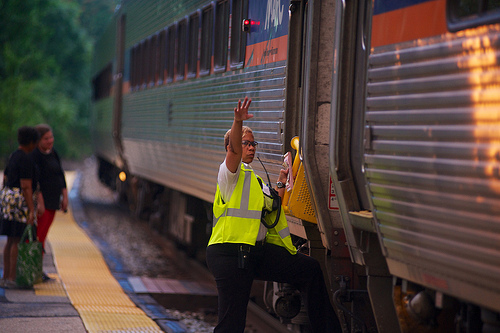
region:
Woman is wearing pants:
[203, 240, 259, 331]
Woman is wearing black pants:
[203, 240, 257, 331]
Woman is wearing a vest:
[207, 157, 299, 255]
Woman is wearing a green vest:
[202, 160, 299, 257]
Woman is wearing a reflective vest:
[206, 160, 299, 257]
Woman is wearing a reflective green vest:
[206, 160, 299, 255]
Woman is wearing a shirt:
[215, 157, 272, 241]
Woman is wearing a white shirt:
[213, 159, 278, 241]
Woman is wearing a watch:
[275, 178, 285, 189]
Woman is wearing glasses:
[224, 138, 261, 150]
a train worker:
[205, 95, 337, 331]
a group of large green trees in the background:
[0, 0, 118, 163]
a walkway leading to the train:
[127, 275, 219, 307]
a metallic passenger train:
[90, 0, 498, 332]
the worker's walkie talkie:
[255, 154, 282, 229]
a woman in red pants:
[35, 123, 67, 290]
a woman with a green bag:
[0, 126, 45, 290]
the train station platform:
[0, 169, 187, 331]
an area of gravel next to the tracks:
[80, 156, 258, 331]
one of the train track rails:
[111, 189, 295, 331]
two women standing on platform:
[0, 120, 72, 287]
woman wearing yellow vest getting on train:
[205, 92, 343, 331]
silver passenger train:
[87, 1, 499, 328]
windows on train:
[122, 2, 251, 96]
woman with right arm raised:
[205, 94, 345, 329]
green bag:
[10, 220, 45, 289]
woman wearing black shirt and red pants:
[39, 116, 69, 260]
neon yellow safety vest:
[205, 164, 303, 254]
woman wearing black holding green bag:
[2, 121, 44, 291]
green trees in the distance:
[1, 0, 100, 160]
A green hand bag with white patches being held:
[13, 218, 48, 300]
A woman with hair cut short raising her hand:
[203, 97, 276, 310]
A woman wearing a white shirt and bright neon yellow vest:
[215, 102, 277, 301]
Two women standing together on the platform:
[9, 115, 62, 283]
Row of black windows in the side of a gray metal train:
[117, 4, 256, 88]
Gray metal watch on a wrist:
[270, 175, 286, 195]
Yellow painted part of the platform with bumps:
[49, 247, 125, 304]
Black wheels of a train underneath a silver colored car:
[128, 175, 200, 237]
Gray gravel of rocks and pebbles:
[115, 224, 158, 274]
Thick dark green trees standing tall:
[3, 4, 73, 149]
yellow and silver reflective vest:
[201, 149, 301, 252]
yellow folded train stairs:
[289, 142, 336, 238]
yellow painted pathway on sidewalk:
[57, 266, 137, 331]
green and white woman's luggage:
[8, 221, 62, 296]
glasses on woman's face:
[242, 135, 269, 155]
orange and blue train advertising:
[245, 10, 302, 65]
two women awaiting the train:
[0, 107, 82, 264]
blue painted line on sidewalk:
[108, 271, 168, 331]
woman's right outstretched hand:
[217, 97, 265, 187]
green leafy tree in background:
[15, 14, 100, 96]